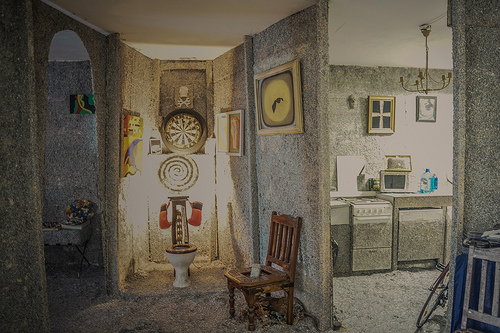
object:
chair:
[223, 210, 303, 330]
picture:
[253, 58, 304, 136]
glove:
[187, 201, 202, 227]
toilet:
[163, 243, 197, 289]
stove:
[340, 196, 393, 271]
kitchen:
[330, 0, 451, 333]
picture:
[415, 95, 436, 121]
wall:
[329, 65, 454, 190]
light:
[395, 24, 451, 93]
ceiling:
[327, 0, 453, 69]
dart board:
[164, 112, 202, 149]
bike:
[415, 260, 450, 326]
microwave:
[380, 171, 419, 193]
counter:
[375, 192, 453, 270]